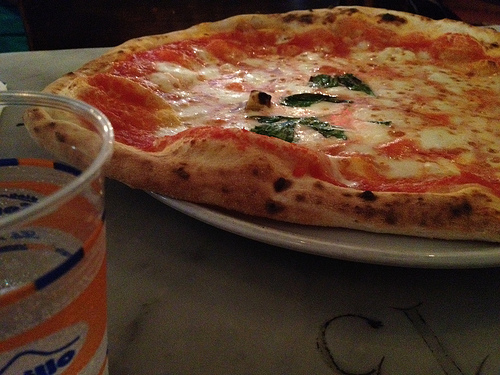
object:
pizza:
[24, 2, 500, 249]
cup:
[0, 90, 117, 372]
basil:
[280, 90, 356, 107]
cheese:
[127, 36, 500, 186]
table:
[0, 27, 497, 374]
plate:
[147, 171, 499, 272]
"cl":
[316, 300, 492, 374]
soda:
[0, 153, 108, 374]